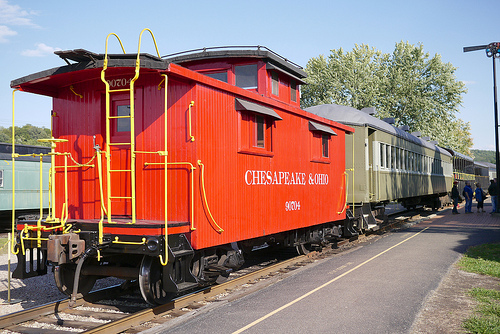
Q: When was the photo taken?
A: Daytime.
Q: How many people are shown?
A: Four.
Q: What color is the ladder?
A: Yellow.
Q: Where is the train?
A: Tracks.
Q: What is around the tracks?
A: Gravel.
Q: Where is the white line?
A: Pavement.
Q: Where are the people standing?
A: Beside train.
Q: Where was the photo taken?
A: At the train depot.